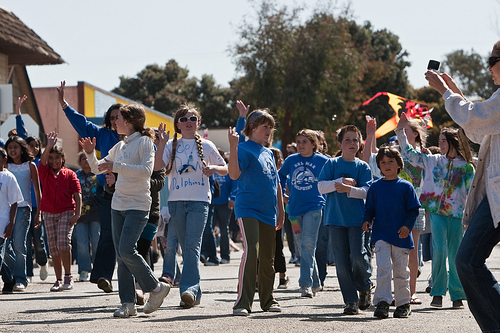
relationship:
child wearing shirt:
[77, 102, 173, 321] [44, 175, 71, 211]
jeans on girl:
[167, 205, 207, 287] [160, 92, 235, 296]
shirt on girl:
[38, 169, 79, 211] [34, 129, 87, 295]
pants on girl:
[231, 215, 278, 314] [34, 127, 82, 292]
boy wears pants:
[361, 144, 424, 319] [230, 215, 286, 312]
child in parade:
[77, 104, 172, 316] [0, 80, 475, 316]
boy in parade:
[358, 145, 422, 320] [0, 80, 475, 316]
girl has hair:
[151, 101, 230, 309] [161, 101, 212, 176]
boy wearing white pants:
[358, 145, 422, 320] [363, 233, 417, 315]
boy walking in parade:
[358, 145, 422, 320] [42, 66, 442, 326]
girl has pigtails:
[151, 104, 231, 309] [167, 96, 217, 208]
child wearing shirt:
[77, 102, 173, 321] [170, 139, 227, 192]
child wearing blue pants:
[77, 102, 173, 321] [167, 199, 207, 296]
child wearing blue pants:
[77, 102, 173, 321] [6, 205, 30, 287]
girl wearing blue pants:
[279, 128, 322, 294] [111, 210, 148, 301]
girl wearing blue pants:
[275, 125, 332, 299] [286, 211, 320, 286]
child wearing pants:
[77, 102, 173, 321] [45, 200, 103, 254]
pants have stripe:
[233, 215, 278, 312] [233, 218, 252, 302]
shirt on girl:
[235, 137, 281, 212] [223, 86, 290, 329]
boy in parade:
[358, 145, 422, 320] [15, 90, 484, 295]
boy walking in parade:
[358, 145, 422, 320] [13, 50, 487, 306]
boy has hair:
[358, 145, 422, 320] [380, 139, 405, 175]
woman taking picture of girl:
[407, 24, 498, 328] [275, 125, 332, 299]